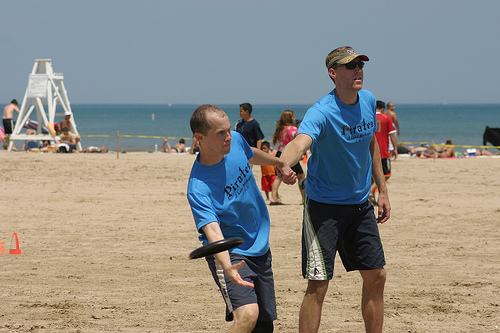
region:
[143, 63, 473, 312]
two matching men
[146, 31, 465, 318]
people at the beach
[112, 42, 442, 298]
two men wearing same shirt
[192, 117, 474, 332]
two men in blue shirts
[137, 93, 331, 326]
man throwing a frisbee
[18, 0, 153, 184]
lifeguard chair at the beach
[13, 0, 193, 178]
white lifeguard chair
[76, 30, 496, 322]
people enjoying the sun at the beach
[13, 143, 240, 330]
dry sand on the beach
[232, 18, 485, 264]
man wearing a hat to be shady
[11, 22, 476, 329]
People playing at the beach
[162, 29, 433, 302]
Two men playing frisbee at the beach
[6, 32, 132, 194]
Lifeguard tower on the beach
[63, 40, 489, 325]
Adult men playing frisbee in blue t-shirts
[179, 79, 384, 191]
Family touring the beach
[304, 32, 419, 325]
Man on beach with shades and cap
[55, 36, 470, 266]
People walking on the shores of the beach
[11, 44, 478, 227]
People sun bathing at the beach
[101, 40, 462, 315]
Two men holding hands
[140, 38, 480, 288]
Man throwing frisbee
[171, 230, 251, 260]
A BLACK FRISBEE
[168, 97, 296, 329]
A MAN CATCHING A FRISBEE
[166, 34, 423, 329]
TWO MEN WEARING FRISBEE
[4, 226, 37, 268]
AN ORANGE CONE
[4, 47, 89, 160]
A LIFE GUARDS CHAIR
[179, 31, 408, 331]
TWO GUYS ON THE BEACH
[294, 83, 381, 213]
A BLUE TEE SHIRT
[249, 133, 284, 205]
A LITTLE BOY IN RED SHORTS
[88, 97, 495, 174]
THE OCEAN IN THE BACKGROUND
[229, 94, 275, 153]
A MAN IN A BLACK TEE SHIRT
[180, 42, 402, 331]
the men are holding hands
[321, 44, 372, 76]
the man is wearing a hat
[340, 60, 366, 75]
the man is wearing sunglasses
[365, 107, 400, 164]
the man is wearing a red shirt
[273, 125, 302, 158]
the woman is wearing a pink shirt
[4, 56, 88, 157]
the lifeguard chair is white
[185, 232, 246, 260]
the frisbee is black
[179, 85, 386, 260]
the men are wearing blue t-shirts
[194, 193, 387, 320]
the men are wearing grey shorts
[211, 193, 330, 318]
the men's shorts have white stripes on them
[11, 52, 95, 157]
Lifeguard chair on beach.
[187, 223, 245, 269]
Frisbee in midair.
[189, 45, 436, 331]
Men playing frisbee.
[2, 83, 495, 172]
Water in the background.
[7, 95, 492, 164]
Beach full of people.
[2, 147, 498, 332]
Sand on the beach.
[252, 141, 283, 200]
Small child in the background.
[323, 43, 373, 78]
Man with ball cap.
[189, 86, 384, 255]
Name of team on blue shirts.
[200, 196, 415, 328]
Men wearing shorts on beach.